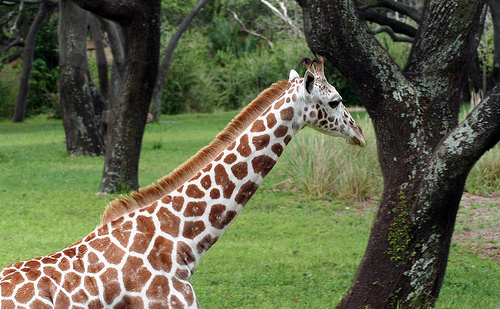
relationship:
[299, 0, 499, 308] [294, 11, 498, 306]
moss on tree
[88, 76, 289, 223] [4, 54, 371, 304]
mane on giraffe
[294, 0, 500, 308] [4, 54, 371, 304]
tree behind giraffe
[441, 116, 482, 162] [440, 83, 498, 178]
bark on branch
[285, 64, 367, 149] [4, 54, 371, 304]
head of giraffe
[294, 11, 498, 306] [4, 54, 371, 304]
tree next to giraffe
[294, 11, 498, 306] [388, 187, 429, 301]
tree with moss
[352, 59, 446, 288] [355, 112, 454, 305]
moss on tree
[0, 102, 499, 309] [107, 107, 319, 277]
green grass behind giraffe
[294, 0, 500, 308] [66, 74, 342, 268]
tree behind giraffe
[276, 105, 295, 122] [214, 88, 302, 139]
spot on giraffe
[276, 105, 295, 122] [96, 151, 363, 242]
spot on giraffe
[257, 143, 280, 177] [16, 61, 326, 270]
spot on giraffe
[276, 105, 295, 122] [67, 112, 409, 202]
spot on giraffe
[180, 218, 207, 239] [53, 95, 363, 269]
spot on giraffe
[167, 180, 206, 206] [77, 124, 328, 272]
spot on giraffe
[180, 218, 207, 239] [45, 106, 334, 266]
spot on giraffe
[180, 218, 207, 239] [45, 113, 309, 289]
spot on giraffe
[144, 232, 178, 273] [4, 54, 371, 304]
spot on giraffe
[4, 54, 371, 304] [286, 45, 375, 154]
giraffe has head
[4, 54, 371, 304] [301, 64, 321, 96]
giraffe has ear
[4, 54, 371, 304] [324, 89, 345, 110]
giraffe has eye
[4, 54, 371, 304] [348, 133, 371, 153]
giraffe has mouth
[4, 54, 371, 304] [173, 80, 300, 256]
giraffe has neck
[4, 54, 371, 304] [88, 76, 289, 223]
giraffe has mane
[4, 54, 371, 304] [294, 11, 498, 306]
giraffe near tree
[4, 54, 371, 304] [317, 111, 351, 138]
giraffe has jaw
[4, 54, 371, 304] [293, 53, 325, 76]
giraffe has horns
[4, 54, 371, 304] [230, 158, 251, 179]
giraffe has spot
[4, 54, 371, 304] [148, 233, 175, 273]
giraffe has spot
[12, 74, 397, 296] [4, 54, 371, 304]
green grass behind giraffe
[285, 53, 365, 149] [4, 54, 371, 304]
head of giraffe